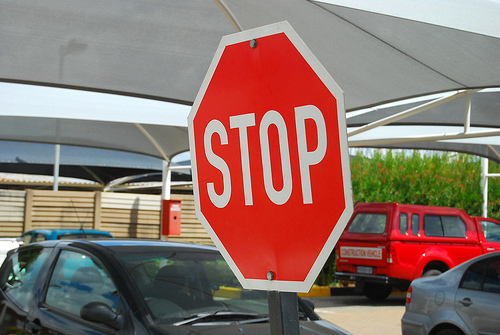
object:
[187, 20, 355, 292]
stop sign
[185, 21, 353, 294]
border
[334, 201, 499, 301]
truck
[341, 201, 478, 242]
camper shell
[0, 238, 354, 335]
car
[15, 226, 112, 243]
vehicle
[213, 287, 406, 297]
curb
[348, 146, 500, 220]
hedges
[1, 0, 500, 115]
roof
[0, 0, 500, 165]
sky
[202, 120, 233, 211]
letters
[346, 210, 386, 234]
back window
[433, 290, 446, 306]
gas tank door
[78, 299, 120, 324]
side mirror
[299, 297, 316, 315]
side mirror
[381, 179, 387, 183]
flowers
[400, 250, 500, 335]
vehicles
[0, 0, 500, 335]
lot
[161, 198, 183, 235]
box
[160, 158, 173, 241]
pole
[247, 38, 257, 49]
bolt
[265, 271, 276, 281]
bolt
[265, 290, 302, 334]
pole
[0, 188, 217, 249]
fence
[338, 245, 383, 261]
sign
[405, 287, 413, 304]
brake light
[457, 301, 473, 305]
door handle